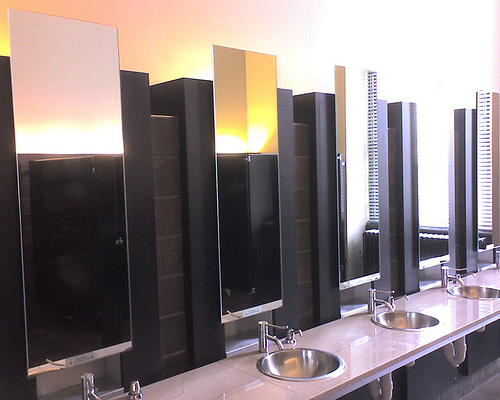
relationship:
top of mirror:
[8, 9, 120, 33] [9, 6, 132, 378]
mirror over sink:
[212, 44, 282, 326] [257, 346, 345, 383]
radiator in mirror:
[420, 233, 449, 263] [332, 66, 379, 293]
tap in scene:
[367, 287, 395, 314] [0, 2, 499, 399]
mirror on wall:
[9, 6, 132, 378] [1, 56, 36, 400]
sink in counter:
[257, 346, 345, 383] [105, 266, 500, 400]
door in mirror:
[30, 155, 131, 367] [9, 6, 132, 378]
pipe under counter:
[444, 337, 469, 367] [105, 266, 500, 400]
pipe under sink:
[371, 367, 402, 397] [243, 310, 355, 400]